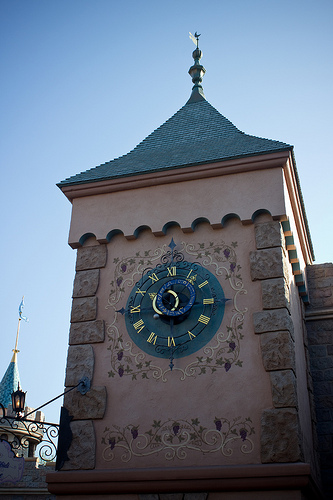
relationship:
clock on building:
[115, 236, 233, 372] [84, 135, 296, 435]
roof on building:
[81, 91, 309, 167] [62, 94, 315, 469]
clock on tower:
[115, 236, 233, 372] [40, 75, 308, 482]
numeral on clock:
[130, 266, 214, 347] [115, 236, 233, 372]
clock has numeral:
[115, 236, 233, 372] [130, 266, 214, 347]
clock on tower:
[132, 255, 234, 370] [44, 31, 315, 497]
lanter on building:
[10, 381, 27, 418] [44, 14, 332, 497]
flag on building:
[18, 298, 27, 320] [1, 295, 55, 497]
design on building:
[98, 415, 256, 459] [45, 31, 333, 500]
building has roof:
[45, 31, 333, 500] [55, 31, 316, 265]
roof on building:
[55, 31, 316, 265] [0, 150, 332, 498]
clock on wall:
[115, 236, 233, 372] [61, 172, 303, 466]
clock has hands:
[115, 236, 233, 372] [144, 287, 206, 316]